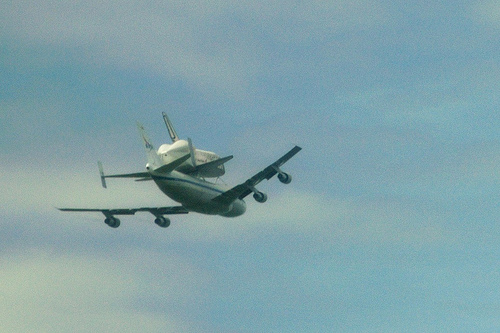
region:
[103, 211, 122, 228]
the large engine of the plane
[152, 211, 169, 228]
the large engine of the plane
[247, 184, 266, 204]
the large engine of the plane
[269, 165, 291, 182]
the large engine of the plane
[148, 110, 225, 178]
the space shuttle on top of the plane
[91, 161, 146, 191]
the tail of the plane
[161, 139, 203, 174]
the tail of the plane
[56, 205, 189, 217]
the wing of the plane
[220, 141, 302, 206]
the wing of the plane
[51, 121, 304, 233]
the blue and white plane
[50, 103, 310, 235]
a plane carrying a shuttle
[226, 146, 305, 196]
right wing of a plane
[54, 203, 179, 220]
left wing of a plane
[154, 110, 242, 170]
a white shuttle on a plane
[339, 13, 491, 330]
a blue and gray sky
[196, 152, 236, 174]
a wing on a shuttle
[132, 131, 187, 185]
the tail wings of a plane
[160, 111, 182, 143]
the tail wing of a shuttle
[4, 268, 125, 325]
white clouds in the sky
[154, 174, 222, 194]
a blue strip on a plane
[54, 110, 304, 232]
a jumbo jet with another one on top of it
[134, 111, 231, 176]
smaller jet placed on top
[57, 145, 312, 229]
larger jet underneath as a propeller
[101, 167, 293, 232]
four jet exhausts of the large plane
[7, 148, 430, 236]
cloud formation in the back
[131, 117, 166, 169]
tail of the larger jet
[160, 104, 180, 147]
tail of the smaller jet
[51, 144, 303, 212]
wingspan of the larger jet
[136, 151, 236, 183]
wingspan of the smaller jet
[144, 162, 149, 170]
tail light of the larger jet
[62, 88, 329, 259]
two planes are flying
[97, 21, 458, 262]
the sky is partly cloudy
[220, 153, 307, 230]
engines are on the wing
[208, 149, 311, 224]
two engines on the wing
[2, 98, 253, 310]
the clouds are white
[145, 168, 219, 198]
a stripe on the plane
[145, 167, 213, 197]
the stripe is dark colored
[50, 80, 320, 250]
the planes are flying high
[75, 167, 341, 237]
there are four engines all together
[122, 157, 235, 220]
the plane is mostly grey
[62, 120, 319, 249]
these are the planes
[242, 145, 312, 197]
this is a plane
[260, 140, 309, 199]
the plane is sharp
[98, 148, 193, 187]
this is a tail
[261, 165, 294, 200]
these are the propellers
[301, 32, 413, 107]
this is the sky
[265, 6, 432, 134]
the sky is blue in color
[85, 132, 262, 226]
they are two in number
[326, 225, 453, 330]
the sky is blue in color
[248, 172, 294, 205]
the propellers are two in number